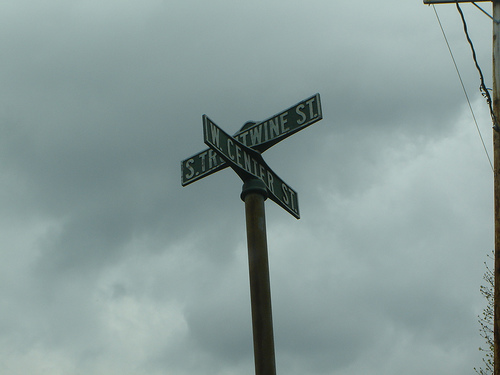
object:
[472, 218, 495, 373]
branches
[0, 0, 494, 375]
clouds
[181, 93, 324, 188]
sign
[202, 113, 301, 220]
sign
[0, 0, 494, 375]
sky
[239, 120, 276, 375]
metal pole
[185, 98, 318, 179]
twine st.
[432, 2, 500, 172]
wires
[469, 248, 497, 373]
corner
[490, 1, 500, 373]
pole